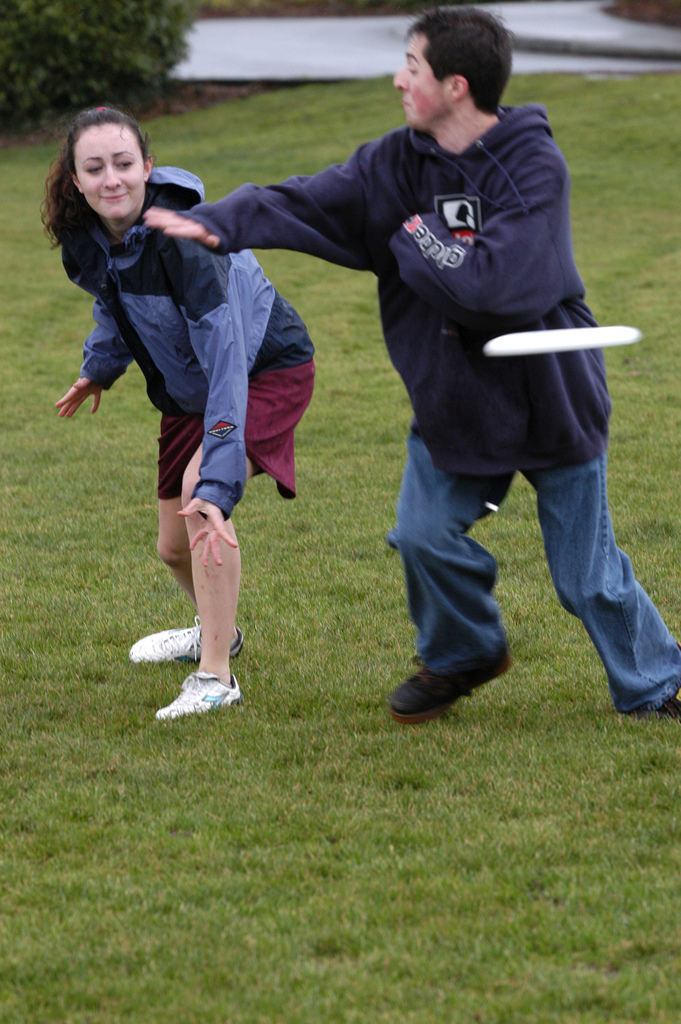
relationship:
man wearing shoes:
[142, 16, 675, 729] [389, 638, 677, 733]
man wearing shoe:
[142, 16, 675, 729] [389, 643, 513, 724]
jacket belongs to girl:
[62, 156, 320, 414] [39, 97, 333, 739]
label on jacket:
[202, 414, 245, 448] [62, 156, 320, 414]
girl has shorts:
[39, 97, 333, 739] [157, 359, 316, 500]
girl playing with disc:
[39, 107, 315, 719] [462, 319, 652, 363]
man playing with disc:
[142, 5, 680, 725] [462, 319, 652, 363]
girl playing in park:
[39, 107, 315, 719] [3, 4, 674, 1023]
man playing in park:
[142, 5, 680, 725] [3, 4, 674, 1023]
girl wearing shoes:
[39, 97, 333, 739] [115, 619, 251, 725]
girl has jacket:
[39, 107, 315, 719] [75, 156, 321, 428]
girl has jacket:
[39, 107, 315, 719] [52, 160, 334, 527]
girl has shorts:
[39, 107, 315, 719] [150, 349, 320, 514]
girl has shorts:
[39, 107, 315, 719] [145, 346, 327, 525]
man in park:
[142, 5, 680, 725] [188, 746, 438, 906]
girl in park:
[39, 107, 315, 719] [188, 746, 438, 906]